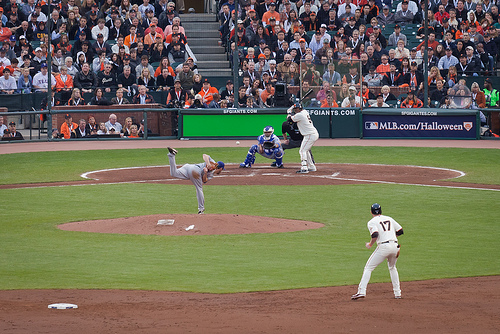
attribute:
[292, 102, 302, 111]
helmet — black, blue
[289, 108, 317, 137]
shirt — white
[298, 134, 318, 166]
pants — white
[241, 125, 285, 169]
catcher — crouched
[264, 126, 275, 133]
helmet — blue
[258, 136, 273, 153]
chest guard — blue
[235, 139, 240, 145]
baseball — white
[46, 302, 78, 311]
second base — white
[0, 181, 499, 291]
infield grass — green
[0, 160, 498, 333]
infield dirt — tan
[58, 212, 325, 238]
pitching mound — dusty, dirt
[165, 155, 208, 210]
pants — dirty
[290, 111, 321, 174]
uniform — white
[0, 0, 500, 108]
crowd — watching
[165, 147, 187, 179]
leg — bent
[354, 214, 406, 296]
uniform — white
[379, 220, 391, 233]
number — 17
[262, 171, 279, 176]
home plate — white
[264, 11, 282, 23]
shirt — orange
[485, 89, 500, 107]
shirt — green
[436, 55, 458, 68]
shirt — blue